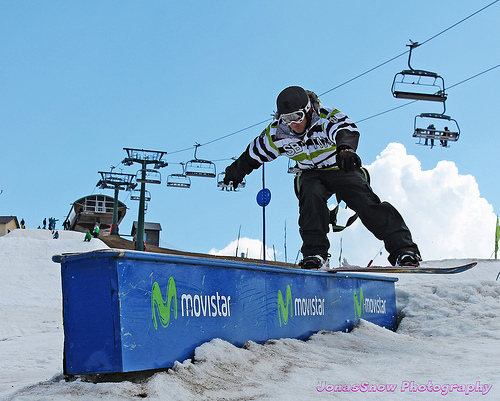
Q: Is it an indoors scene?
A: Yes, it is indoors.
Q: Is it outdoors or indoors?
A: It is indoors.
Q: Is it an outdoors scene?
A: No, it is indoors.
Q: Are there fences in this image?
A: No, there are no fences.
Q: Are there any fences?
A: No, there are no fences.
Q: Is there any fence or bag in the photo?
A: No, there are no fences or bags.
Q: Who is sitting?
A: The people are sitting.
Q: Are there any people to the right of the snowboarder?
A: Yes, there are people to the right of the snowboarder.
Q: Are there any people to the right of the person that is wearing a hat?
A: Yes, there are people to the right of the snowboarder.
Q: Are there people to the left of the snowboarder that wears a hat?
A: No, the people are to the right of the snowboarder.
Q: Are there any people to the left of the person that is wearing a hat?
A: No, the people are to the right of the snowboarder.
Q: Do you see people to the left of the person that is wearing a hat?
A: No, the people are to the right of the snowboarder.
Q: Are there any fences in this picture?
A: No, there are no fences.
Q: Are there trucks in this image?
A: No, there are no trucks.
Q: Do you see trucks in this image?
A: No, there are no trucks.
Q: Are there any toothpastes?
A: No, there are no toothpastes.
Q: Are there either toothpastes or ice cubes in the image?
A: No, there are no toothpastes or ice cubes.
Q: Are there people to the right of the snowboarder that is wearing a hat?
A: Yes, there is a person to the right of the snowboarder.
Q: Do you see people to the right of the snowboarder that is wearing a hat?
A: Yes, there is a person to the right of the snowboarder.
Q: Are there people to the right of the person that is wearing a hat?
A: Yes, there is a person to the right of the snowboarder.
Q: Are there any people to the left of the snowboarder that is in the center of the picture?
A: No, the person is to the right of the snowboarder.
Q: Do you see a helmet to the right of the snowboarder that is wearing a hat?
A: No, there is a person to the right of the snowboarder.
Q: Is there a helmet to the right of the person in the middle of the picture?
A: No, there is a person to the right of the snowboarder.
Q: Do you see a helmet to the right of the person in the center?
A: No, there is a person to the right of the snowboarder.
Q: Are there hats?
A: Yes, there is a hat.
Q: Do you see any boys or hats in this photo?
A: Yes, there is a hat.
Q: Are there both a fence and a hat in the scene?
A: No, there is a hat but no fences.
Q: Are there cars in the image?
A: No, there are no cars.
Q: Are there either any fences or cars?
A: No, there are no cars or fences.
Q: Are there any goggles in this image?
A: Yes, there are goggles.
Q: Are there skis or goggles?
A: Yes, there are goggles.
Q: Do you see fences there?
A: No, there are no fences.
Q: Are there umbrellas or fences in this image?
A: No, there are no fences or umbrellas.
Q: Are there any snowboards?
A: Yes, there is a snowboard.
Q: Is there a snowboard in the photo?
A: Yes, there is a snowboard.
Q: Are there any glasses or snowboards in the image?
A: Yes, there is a snowboard.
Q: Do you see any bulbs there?
A: No, there are no bulbs.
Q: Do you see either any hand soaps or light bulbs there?
A: No, there are no light bulbs or hand soaps.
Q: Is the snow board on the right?
A: Yes, the snow board is on the right of the image.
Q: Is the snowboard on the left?
A: No, the snowboard is on the right of the image.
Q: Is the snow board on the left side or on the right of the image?
A: The snow board is on the right of the image.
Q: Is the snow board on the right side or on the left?
A: The snow board is on the right of the image.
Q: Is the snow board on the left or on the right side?
A: The snow board is on the right of the image.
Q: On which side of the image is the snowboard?
A: The snowboard is on the right of the image.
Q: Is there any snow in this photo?
A: Yes, there is snow.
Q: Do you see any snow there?
A: Yes, there is snow.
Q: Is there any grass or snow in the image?
A: Yes, there is snow.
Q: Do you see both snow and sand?
A: No, there is snow but no sand.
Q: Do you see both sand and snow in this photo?
A: No, there is snow but no sand.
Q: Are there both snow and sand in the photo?
A: No, there is snow but no sand.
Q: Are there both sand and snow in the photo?
A: No, there is snow but no sand.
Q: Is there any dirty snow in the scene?
A: Yes, there is dirty snow.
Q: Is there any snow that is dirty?
A: Yes, there is snow that is dirty.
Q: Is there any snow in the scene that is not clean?
A: Yes, there is dirty snow.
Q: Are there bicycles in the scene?
A: No, there are no bicycles.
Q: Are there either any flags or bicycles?
A: No, there are no bicycles or flags.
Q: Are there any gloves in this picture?
A: Yes, there are gloves.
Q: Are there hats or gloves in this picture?
A: Yes, there are gloves.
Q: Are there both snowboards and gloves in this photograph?
A: Yes, there are both gloves and a snowboard.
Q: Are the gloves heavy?
A: Yes, the gloves are heavy.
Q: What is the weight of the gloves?
A: The gloves are heavy.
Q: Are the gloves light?
A: No, the gloves are heavy.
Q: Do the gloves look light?
A: No, the gloves are heavy.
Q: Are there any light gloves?
A: No, there are gloves but they are heavy.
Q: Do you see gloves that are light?
A: No, there are gloves but they are heavy.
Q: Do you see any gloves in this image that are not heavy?
A: No, there are gloves but they are heavy.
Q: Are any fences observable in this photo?
A: No, there are no fences.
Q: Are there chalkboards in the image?
A: No, there are no chalkboards.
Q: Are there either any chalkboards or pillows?
A: No, there are no chalkboards or pillows.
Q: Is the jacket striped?
A: Yes, the jacket is striped.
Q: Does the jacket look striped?
A: Yes, the jacket is striped.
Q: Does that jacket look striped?
A: Yes, the jacket is striped.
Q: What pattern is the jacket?
A: The jacket is striped.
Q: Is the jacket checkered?
A: No, the jacket is striped.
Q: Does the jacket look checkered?
A: No, the jacket is striped.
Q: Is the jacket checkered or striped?
A: The jacket is striped.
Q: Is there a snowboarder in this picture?
A: Yes, there is a snowboarder.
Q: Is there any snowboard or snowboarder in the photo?
A: Yes, there is a snowboarder.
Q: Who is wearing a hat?
A: The snowboarder is wearing a hat.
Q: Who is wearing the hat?
A: The snowboarder is wearing a hat.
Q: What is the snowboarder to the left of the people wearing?
A: The snowboarder is wearing a hat.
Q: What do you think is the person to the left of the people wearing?
A: The snowboarder is wearing a hat.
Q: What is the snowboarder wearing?
A: The snowboarder is wearing a hat.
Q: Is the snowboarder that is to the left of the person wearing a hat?
A: Yes, the snowboarder is wearing a hat.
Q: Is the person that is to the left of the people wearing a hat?
A: Yes, the snowboarder is wearing a hat.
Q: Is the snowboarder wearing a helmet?
A: No, the snowboarder is wearing a hat.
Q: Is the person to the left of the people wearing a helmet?
A: No, the snowboarder is wearing a hat.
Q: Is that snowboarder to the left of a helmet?
A: No, the snowboarder is to the left of a person.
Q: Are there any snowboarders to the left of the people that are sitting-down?
A: Yes, there is a snowboarder to the left of the people.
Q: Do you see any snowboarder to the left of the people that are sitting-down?
A: Yes, there is a snowboarder to the left of the people.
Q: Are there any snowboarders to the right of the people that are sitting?
A: No, the snowboarder is to the left of the people.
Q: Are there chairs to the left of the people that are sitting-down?
A: No, there is a snowboarder to the left of the people.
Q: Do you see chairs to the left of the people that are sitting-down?
A: No, there is a snowboarder to the left of the people.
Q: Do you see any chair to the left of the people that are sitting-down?
A: No, there is a snowboarder to the left of the people.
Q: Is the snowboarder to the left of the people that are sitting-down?
A: Yes, the snowboarder is to the left of the people.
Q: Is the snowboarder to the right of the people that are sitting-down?
A: No, the snowboarder is to the left of the people.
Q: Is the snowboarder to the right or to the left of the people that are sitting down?
A: The snowboarder is to the left of the people.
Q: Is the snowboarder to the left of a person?
A: Yes, the snowboarder is to the left of a person.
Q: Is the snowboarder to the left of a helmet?
A: No, the snowboarder is to the left of a person.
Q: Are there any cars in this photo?
A: No, there are no cars.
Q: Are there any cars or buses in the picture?
A: No, there are no cars or buses.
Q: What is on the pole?
A: The sign is on the pole.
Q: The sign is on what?
A: The sign is on the pole.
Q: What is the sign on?
A: The sign is on the pole.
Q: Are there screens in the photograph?
A: No, there are no screens.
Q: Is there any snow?
A: Yes, there is snow.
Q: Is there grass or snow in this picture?
A: Yes, there is snow.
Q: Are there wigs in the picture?
A: No, there are no wigs.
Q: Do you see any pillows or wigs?
A: No, there are no wigs or pillows.